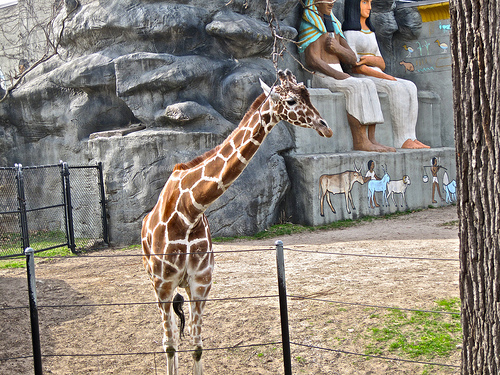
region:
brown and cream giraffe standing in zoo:
[140, 65, 339, 372]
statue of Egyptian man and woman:
[293, 0, 432, 156]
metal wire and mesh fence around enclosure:
[0, 152, 476, 369]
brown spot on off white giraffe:
[221, 153, 246, 190]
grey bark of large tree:
[435, 0, 497, 370]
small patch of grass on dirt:
[361, 287, 472, 367]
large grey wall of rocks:
[8, 0, 305, 240]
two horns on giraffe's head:
[271, 67, 296, 85]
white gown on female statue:
[336, 23, 431, 143]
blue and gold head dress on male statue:
[291, 0, 351, 54]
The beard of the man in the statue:
[323, 9, 333, 36]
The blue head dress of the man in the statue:
[302, 13, 347, 50]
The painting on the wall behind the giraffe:
[320, 159, 455, 219]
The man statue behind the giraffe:
[303, 15, 381, 152]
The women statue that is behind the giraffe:
[337, 6, 424, 157]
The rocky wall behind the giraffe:
[26, 22, 276, 240]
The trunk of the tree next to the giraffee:
[445, 13, 499, 367]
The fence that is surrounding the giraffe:
[13, 153, 493, 371]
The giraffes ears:
[252, 68, 313, 96]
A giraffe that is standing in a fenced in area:
[140, 69, 334, 364]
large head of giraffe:
[233, 65, 335, 148]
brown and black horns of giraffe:
[272, 68, 295, 78]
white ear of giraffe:
[254, 73, 271, 97]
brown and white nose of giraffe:
[310, 118, 337, 139]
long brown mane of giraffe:
[244, 94, 271, 114]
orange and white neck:
[182, 109, 272, 184]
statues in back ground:
[290, 4, 422, 161]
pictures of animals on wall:
[293, 156, 418, 228]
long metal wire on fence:
[40, 295, 269, 317]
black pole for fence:
[16, 254, 44, 374]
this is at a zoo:
[40, 37, 400, 372]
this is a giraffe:
[80, 81, 348, 371]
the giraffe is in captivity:
[123, 78, 296, 261]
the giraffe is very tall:
[134, 85, 266, 322]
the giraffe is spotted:
[127, 159, 206, 278]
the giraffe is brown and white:
[144, 157, 247, 297]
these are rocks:
[63, 22, 200, 207]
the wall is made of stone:
[67, 40, 159, 147]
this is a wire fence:
[44, 258, 227, 368]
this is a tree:
[440, 43, 498, 167]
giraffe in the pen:
[110, 60, 322, 368]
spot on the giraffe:
[168, 217, 190, 237]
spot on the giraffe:
[198, 272, 208, 285]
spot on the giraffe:
[197, 182, 217, 204]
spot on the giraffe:
[222, 159, 241, 177]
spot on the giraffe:
[188, 185, 206, 201]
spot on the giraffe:
[185, 173, 195, 188]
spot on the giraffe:
[161, 264, 188, 284]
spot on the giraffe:
[144, 207, 155, 221]